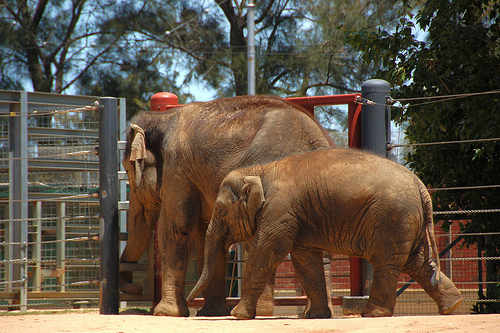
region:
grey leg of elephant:
[155, 187, 190, 315]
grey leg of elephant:
[230, 224, 302, 319]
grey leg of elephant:
[195, 230, 228, 315]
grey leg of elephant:
[290, 244, 331, 319]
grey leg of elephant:
[362, 247, 394, 316]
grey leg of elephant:
[415, 260, 464, 314]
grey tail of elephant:
[415, 185, 439, 285]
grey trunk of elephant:
[186, 224, 225, 306]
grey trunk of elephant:
[115, 176, 157, 293]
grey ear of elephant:
[243, 179, 268, 221]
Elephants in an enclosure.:
[11, 28, 491, 328]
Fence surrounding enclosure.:
[6, 64, 492, 313]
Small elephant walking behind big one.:
[61, 77, 468, 320]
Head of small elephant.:
[201, 154, 266, 251]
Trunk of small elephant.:
[186, 210, 224, 306]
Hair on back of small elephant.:
[236, 142, 369, 178]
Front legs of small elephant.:
[231, 233, 337, 318]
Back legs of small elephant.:
[358, 233, 463, 314]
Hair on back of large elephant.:
[123, 93, 294, 132]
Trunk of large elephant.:
[103, 202, 155, 299]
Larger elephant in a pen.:
[119, 95, 333, 317]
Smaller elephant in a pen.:
[186, 149, 463, 313]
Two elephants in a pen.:
[117, 94, 464, 316]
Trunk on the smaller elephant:
[187, 217, 223, 298]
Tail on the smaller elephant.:
[419, 180, 441, 282]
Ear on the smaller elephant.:
[242, 175, 264, 230]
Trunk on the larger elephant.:
[119, 198, 146, 292]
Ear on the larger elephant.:
[129, 123, 143, 185]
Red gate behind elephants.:
[148, 90, 362, 305]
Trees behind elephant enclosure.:
[3, 0, 499, 92]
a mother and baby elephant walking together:
[131, 109, 475, 299]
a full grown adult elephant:
[81, 101, 254, 314]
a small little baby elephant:
[212, 165, 452, 307]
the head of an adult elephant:
[109, 123, 171, 259]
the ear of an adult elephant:
[115, 129, 169, 178]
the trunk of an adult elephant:
[97, 185, 150, 306]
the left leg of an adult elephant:
[150, 206, 192, 321]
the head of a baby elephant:
[193, 180, 280, 255]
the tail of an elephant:
[411, 178, 457, 290]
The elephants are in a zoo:
[16, 26, 496, 311]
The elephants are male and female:
[35, 35, 476, 290]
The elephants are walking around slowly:
[60, 72, 480, 307]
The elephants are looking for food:
[52, 53, 472, 314]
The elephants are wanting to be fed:
[41, 37, 467, 317]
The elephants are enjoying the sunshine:
[37, 53, 477, 316]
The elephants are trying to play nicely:
[45, 45, 496, 321]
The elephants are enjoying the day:
[36, 57, 489, 318]